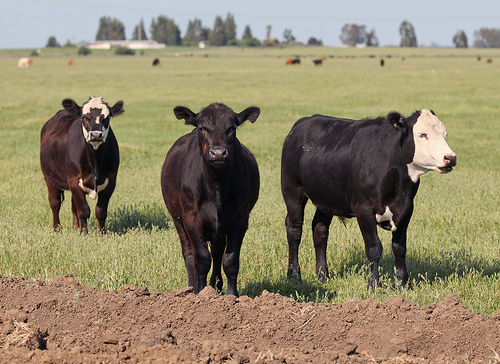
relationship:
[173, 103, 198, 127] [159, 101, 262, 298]
ear of cow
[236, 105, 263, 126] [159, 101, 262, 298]
ear of cow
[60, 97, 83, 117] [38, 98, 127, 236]
ear of cow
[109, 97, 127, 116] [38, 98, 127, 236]
ear of cow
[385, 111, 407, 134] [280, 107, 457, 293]
ear of cow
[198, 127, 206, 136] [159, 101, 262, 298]
eye of cow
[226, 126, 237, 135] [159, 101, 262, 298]
eye of cow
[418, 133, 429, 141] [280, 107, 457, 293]
eye of cow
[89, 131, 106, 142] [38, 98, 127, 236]
nose of cow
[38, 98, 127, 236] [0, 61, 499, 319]
cow in field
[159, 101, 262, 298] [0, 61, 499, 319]
cow in field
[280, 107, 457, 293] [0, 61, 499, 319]
cow in field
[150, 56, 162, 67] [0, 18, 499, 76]
cow in distance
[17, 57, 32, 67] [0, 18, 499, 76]
cow in distance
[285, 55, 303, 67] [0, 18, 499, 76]
cow in distance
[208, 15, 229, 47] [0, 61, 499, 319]
tree in back of field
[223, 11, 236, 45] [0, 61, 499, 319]
tree in back of field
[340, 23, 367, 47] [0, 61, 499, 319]
tree in back of field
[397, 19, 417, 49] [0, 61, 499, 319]
tree in back of field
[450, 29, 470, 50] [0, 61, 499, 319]
tree in back of field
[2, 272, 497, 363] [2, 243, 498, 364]
dirt on ground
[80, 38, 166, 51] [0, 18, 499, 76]
building in distance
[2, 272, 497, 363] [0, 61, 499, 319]
dirt next to field